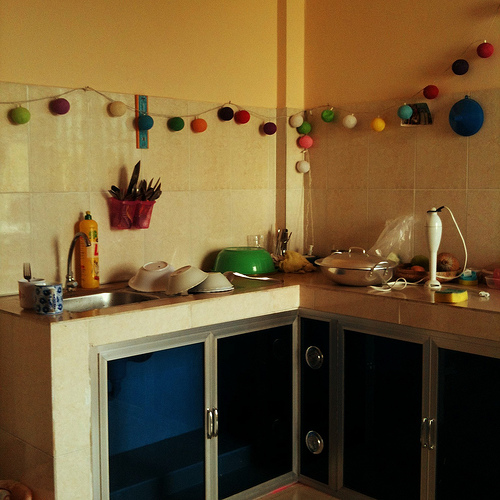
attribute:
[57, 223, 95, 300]
faucet — chrome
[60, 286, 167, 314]
sink — metal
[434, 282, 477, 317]
sponge. — yellow, green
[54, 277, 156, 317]
sink — on a stand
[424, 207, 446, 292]
hand mixer — white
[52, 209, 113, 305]
faucet — curved, kitchen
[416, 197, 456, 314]
blender — white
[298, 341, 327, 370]
round object — on a stand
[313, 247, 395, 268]
lid — clear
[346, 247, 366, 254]
handle — silver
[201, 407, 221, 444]
handles — counter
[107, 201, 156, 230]
basket — red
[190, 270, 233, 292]
bowl — white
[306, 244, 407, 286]
pan — chrome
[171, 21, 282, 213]
wall — counter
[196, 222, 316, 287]
bowl — green, flipped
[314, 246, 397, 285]
pot — silver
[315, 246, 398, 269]
lid — silver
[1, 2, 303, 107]
wall — yellow 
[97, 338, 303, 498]
cabinets — blue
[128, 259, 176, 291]
bowl — upside down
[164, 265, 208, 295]
bowl — upside down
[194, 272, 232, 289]
bowl — upside down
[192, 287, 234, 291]
bowl — upside down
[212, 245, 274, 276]
bowl — large, green, upside down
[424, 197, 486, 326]
mixer — on a stand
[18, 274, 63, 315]
mugs — coffee